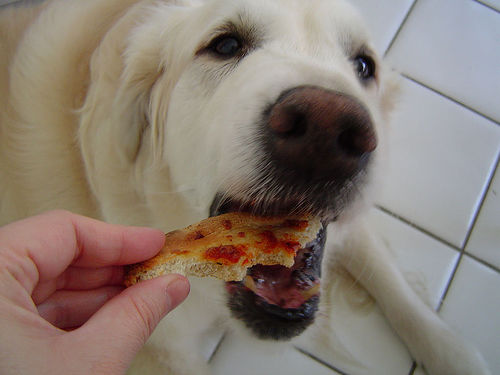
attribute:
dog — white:
[2, 3, 495, 366]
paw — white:
[416, 343, 484, 370]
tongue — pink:
[244, 265, 316, 316]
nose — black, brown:
[277, 87, 375, 179]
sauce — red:
[203, 244, 245, 263]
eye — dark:
[352, 45, 399, 81]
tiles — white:
[352, 72, 498, 259]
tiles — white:
[376, 1, 498, 130]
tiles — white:
[432, 245, 499, 349]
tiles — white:
[288, 203, 461, 372]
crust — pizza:
[123, 201, 323, 287]